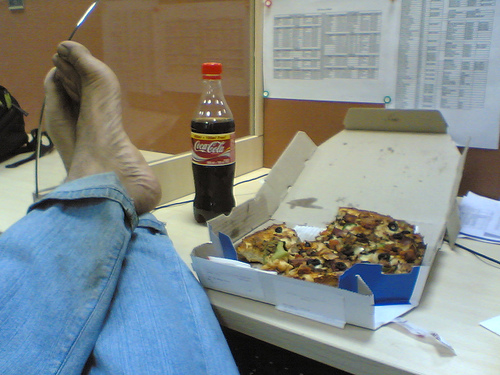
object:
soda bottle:
[190, 61, 238, 228]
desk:
[0, 132, 500, 375]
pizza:
[259, 206, 425, 287]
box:
[188, 107, 470, 332]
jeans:
[0, 170, 241, 375]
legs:
[1, 171, 139, 375]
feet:
[49, 39, 162, 215]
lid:
[200, 61, 222, 75]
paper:
[260, 0, 393, 104]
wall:
[262, 1, 500, 200]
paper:
[385, 0, 500, 151]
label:
[190, 131, 237, 167]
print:
[272, 7, 381, 83]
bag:
[0, 85, 30, 164]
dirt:
[74, 182, 139, 292]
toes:
[56, 41, 92, 68]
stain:
[284, 195, 324, 213]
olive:
[334, 261, 347, 271]